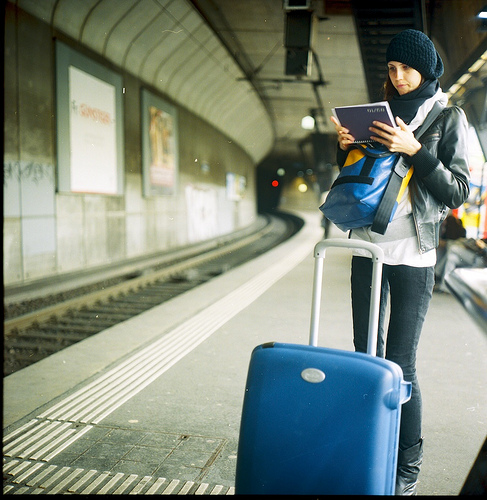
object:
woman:
[330, 30, 469, 500]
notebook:
[335, 106, 393, 140]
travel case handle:
[308, 237, 383, 356]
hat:
[386, 29, 444, 81]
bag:
[320, 144, 414, 231]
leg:
[350, 255, 388, 358]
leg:
[387, 261, 434, 450]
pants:
[353, 249, 434, 449]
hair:
[384, 75, 396, 102]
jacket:
[335, 106, 470, 255]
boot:
[392, 439, 423, 497]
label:
[300, 368, 326, 383]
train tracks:
[0, 213, 274, 330]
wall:
[0, 0, 275, 293]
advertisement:
[69, 65, 116, 194]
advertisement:
[148, 104, 176, 188]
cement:
[1, 210, 487, 499]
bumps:
[2, 208, 307, 376]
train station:
[0, 0, 487, 500]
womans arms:
[408, 106, 470, 210]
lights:
[302, 117, 315, 129]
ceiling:
[191, 2, 485, 154]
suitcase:
[232, 238, 415, 500]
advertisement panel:
[55, 42, 125, 197]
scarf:
[388, 79, 440, 125]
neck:
[401, 80, 424, 102]